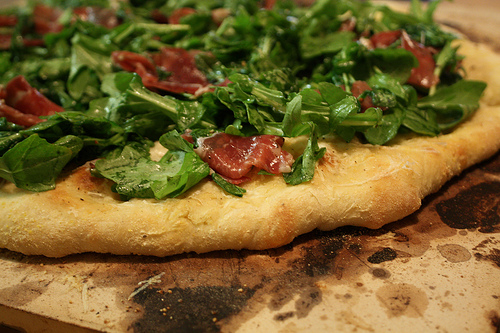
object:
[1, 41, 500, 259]
crust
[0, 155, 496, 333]
table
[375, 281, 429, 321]
grease stain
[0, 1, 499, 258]
pizza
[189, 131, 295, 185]
meat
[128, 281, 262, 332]
spot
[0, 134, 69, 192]
spinach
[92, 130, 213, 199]
spinach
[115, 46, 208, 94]
meat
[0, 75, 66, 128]
meat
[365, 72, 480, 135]
spinach